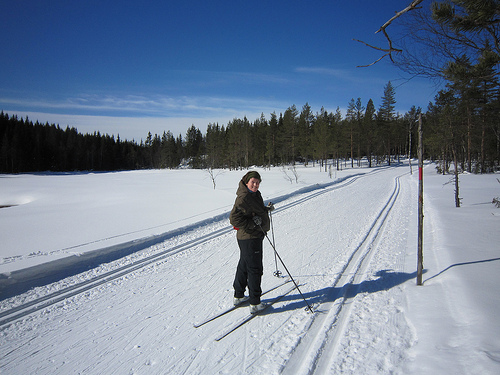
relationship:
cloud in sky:
[20, 96, 372, 148] [2, 1, 497, 146]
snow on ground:
[83, 257, 123, 309] [0, 154, 495, 374]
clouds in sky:
[95, 93, 205, 133] [2, 1, 497, 146]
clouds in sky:
[153, 81, 225, 101] [2, 1, 497, 146]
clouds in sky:
[70, 31, 233, 126] [2, 1, 497, 146]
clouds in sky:
[212, 0, 276, 60] [193, 2, 282, 76]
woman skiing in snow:
[215, 166, 288, 317] [6, 152, 498, 368]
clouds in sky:
[162, 60, 363, 99] [4, 3, 437, 104]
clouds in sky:
[107, 80, 157, 137] [41, 8, 323, 129]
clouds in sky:
[68, 88, 175, 120] [2, 1, 497, 146]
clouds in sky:
[208, 56, 298, 108] [2, 1, 497, 146]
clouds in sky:
[271, 39, 348, 93] [15, 13, 407, 130]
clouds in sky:
[2, 65, 424, 147] [2, 1, 497, 146]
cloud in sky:
[296, 64, 358, 81] [2, 1, 497, 146]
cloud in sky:
[181, 60, 289, 85] [2, 1, 497, 146]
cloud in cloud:
[5, 92, 157, 112] [296, 64, 358, 81]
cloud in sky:
[73, 87, 291, 112] [2, 1, 497, 146]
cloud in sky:
[303, 105, 408, 118] [2, 1, 497, 146]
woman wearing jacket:
[194, 153, 359, 350] [203, 186, 288, 242]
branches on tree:
[352, 24, 498, 79] [183, 77, 392, 164]